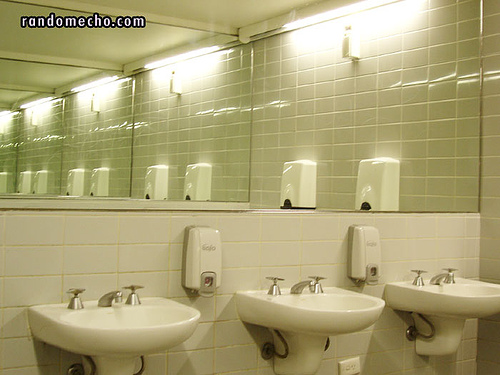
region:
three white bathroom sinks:
[35, 263, 496, 373]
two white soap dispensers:
[184, 226, 382, 301]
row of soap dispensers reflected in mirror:
[2, 159, 407, 206]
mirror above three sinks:
[4, 1, 476, 212]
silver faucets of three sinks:
[98, 267, 474, 299]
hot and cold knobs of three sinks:
[67, 262, 465, 312]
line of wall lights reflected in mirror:
[2, 9, 400, 144]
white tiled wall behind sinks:
[3, 219, 485, 374]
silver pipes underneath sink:
[72, 309, 440, 373]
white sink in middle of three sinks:
[233, 262, 379, 368]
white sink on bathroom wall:
[8, 255, 227, 372]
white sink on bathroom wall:
[237, 266, 379, 370]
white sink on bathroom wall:
[401, 242, 498, 359]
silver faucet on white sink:
[94, 274, 133, 310]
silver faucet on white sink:
[287, 262, 334, 302]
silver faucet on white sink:
[419, 272, 464, 301]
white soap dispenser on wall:
[161, 204, 251, 309]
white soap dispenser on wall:
[338, 224, 402, 294]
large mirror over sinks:
[24, 32, 471, 197]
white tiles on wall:
[41, 217, 473, 372]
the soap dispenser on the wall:
[181, 224, 222, 296]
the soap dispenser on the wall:
[346, 222, 382, 287]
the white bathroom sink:
[384, 267, 499, 356]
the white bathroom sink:
[234, 275, 385, 367]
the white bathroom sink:
[29, 285, 200, 374]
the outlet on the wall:
[338, 356, 363, 374]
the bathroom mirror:
[0, 0, 482, 213]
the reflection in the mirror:
[0, 0, 485, 214]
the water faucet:
[97, 291, 122, 307]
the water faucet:
[290, 279, 313, 296]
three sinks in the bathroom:
[37, 256, 477, 364]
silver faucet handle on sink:
[57, 285, 97, 313]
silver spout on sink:
[101, 291, 125, 313]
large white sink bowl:
[47, 288, 192, 362]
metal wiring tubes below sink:
[58, 357, 162, 374]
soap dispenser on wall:
[172, 222, 226, 308]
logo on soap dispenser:
[197, 236, 229, 256]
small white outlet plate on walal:
[328, 349, 368, 374]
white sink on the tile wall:
[238, 268, 385, 359]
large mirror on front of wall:
[0, 32, 489, 216]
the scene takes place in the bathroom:
[1, 0, 497, 371]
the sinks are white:
[20, 272, 497, 367]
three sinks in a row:
[18, 266, 498, 366]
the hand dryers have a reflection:
[1, 156, 401, 215]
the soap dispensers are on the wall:
[178, 223, 375, 297]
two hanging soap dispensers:
[181, 224, 378, 296]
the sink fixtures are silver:
[63, 267, 456, 311]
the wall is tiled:
[2, 210, 482, 370]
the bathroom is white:
[0, 3, 499, 373]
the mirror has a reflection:
[0, 3, 477, 215]